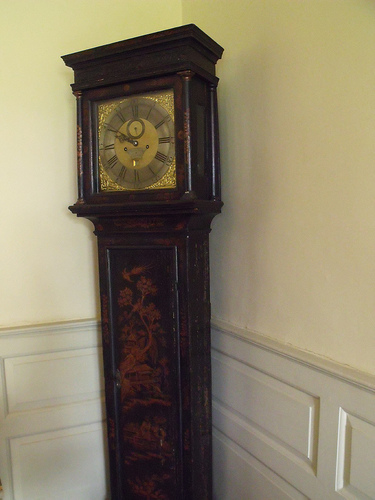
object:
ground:
[305, 112, 334, 151]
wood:
[103, 235, 207, 490]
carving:
[114, 262, 179, 499]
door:
[97, 240, 187, 493]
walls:
[3, 3, 371, 471]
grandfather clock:
[60, 22, 225, 500]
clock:
[91, 77, 187, 195]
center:
[133, 141, 138, 147]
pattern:
[99, 248, 179, 499]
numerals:
[99, 99, 173, 187]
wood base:
[74, 56, 223, 216]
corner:
[173, 0, 187, 25]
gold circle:
[114, 117, 159, 170]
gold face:
[99, 88, 176, 190]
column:
[178, 76, 195, 195]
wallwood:
[53, 90, 370, 378]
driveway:
[96, 88, 176, 195]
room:
[2, 5, 375, 500]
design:
[112, 264, 178, 499]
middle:
[132, 139, 139, 146]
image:
[115, 253, 170, 497]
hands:
[108, 128, 134, 144]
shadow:
[225, 92, 258, 446]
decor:
[101, 232, 193, 500]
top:
[60, 21, 227, 89]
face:
[97, 89, 175, 190]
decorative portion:
[105, 246, 181, 498]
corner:
[82, 239, 223, 489]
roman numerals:
[99, 95, 174, 191]